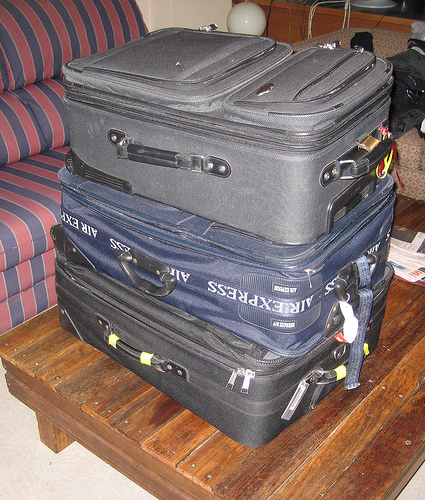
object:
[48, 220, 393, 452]
suitcase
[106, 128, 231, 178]
handle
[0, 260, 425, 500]
table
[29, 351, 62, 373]
line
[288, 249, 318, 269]
zipper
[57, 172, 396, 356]
bag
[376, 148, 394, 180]
word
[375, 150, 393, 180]
tag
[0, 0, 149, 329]
couch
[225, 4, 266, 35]
light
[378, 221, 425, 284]
newspaper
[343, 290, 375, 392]
strap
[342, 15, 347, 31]
chord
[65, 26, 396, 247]
luggage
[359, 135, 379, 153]
tape